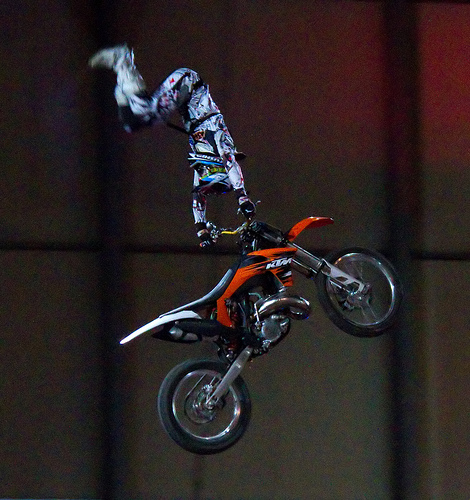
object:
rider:
[88, 45, 261, 235]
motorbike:
[118, 219, 404, 454]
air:
[3, 7, 467, 493]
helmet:
[197, 159, 233, 196]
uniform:
[143, 67, 242, 193]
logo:
[255, 256, 293, 270]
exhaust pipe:
[241, 296, 310, 324]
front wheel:
[318, 245, 408, 338]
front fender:
[291, 208, 334, 242]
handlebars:
[206, 210, 256, 241]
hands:
[191, 211, 213, 241]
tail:
[117, 305, 199, 349]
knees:
[111, 98, 165, 137]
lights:
[259, 218, 285, 246]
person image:
[197, 129, 222, 167]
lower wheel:
[156, 357, 253, 451]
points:
[177, 317, 228, 339]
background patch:
[246, 1, 469, 175]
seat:
[155, 266, 242, 316]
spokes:
[331, 254, 395, 325]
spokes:
[176, 380, 238, 436]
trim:
[240, 266, 269, 276]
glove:
[189, 224, 215, 249]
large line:
[2, 241, 468, 262]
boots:
[87, 42, 143, 110]